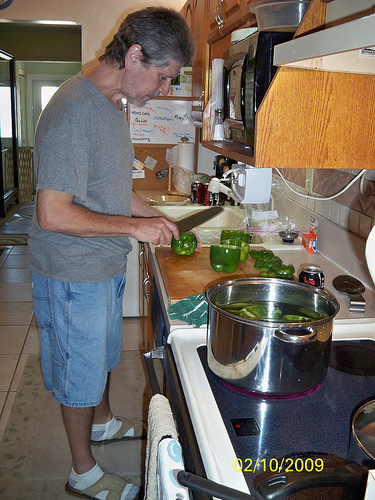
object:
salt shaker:
[211, 109, 225, 141]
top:
[197, 341, 375, 489]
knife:
[172, 207, 223, 236]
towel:
[143, 394, 190, 498]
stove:
[167, 329, 374, 500]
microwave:
[211, 31, 296, 147]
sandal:
[65, 468, 144, 500]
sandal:
[90, 416, 148, 446]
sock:
[90, 416, 135, 441]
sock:
[67, 462, 139, 499]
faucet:
[208, 178, 232, 197]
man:
[25, 6, 201, 499]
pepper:
[171, 231, 197, 255]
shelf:
[202, 0, 375, 168]